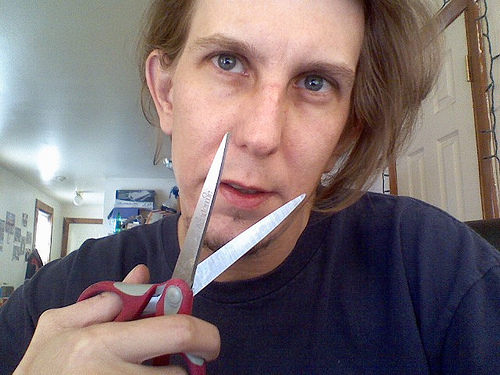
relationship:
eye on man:
[203, 47, 250, 78] [1, 0, 498, 374]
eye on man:
[289, 69, 340, 95] [1, 0, 498, 374]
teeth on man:
[231, 183, 256, 194] [1, 0, 498, 374]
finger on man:
[33, 264, 151, 328] [131, 12, 367, 313]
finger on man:
[105, 312, 218, 363] [1, 0, 498, 374]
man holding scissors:
[142, 2, 444, 373] [54, 127, 316, 353]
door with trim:
[380, 9, 484, 222] [465, 5, 498, 222]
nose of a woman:
[233, 65, 288, 156] [10, 5, 478, 360]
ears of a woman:
[132, 64, 230, 105] [169, 36, 360, 253]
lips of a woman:
[216, 179, 276, 209] [10, 5, 478, 360]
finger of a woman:
[81, 279, 245, 366] [10, 5, 478, 360]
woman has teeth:
[10, 5, 478, 360] [188, 173, 293, 220]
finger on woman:
[33, 264, 151, 328] [10, 5, 478, 360]